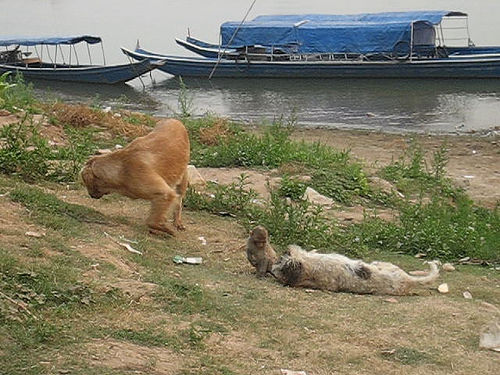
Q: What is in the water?
A: Boat.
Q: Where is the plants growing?
A: In ground.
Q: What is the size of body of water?
A: Large.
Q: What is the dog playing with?
A: Monkey.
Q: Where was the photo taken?
A: Outside somewhere.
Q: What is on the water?
A: Boat.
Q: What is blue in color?
A: Boat.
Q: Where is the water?
A: Next to the boats.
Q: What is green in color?
A: Grass.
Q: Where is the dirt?
A: On the ground.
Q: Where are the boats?
A: On the water.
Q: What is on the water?
A: Boats.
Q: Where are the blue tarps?
A: On the boats.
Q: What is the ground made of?
A: Dirt and grass.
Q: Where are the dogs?
A: On the ground.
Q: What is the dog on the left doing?
A: Standing.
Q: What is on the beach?
A: Weeds.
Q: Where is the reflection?
A: Under the boats.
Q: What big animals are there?
A: Dogs.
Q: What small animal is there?
A: Monkey.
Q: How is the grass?
A: Patchy.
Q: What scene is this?
A: Lake scene.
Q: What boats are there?
A: Blue boats.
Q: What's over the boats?
A: Tarps.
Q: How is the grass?
A: Patchy.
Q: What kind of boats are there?
A: Fishing.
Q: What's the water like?
A: Murky.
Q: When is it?
A: Day time.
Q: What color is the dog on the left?
A: Brown.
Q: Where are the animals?
A: The shore.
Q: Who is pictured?
A: The animals.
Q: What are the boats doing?
A: Floating.